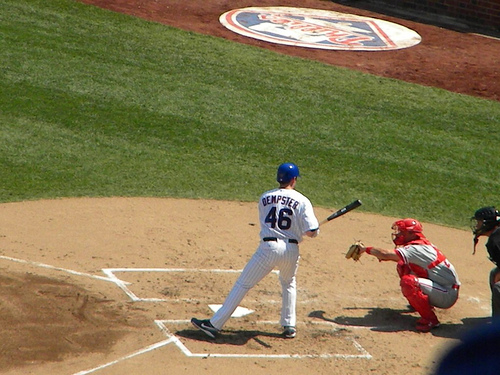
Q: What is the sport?
A: Baseball.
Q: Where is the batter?
A: In front of the catcher.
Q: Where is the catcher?
A: Behind the batter.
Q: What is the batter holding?
A: A baseball bat.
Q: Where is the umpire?
A: Behind the catcher.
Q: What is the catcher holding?
A: A catcher's mitt.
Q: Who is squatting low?
A: The catcher.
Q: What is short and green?
A: The grass.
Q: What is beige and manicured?
A: The dirt.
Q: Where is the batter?
A: At the plate.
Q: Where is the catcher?
A: Behind batter.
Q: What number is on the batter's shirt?
A: 46.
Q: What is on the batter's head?
A: Helmet.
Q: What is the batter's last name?
A: Dempster.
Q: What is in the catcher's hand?
A: Baseball glove.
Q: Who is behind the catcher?
A: Umpire.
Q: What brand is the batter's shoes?
A: Nike.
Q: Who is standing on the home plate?
A: Batter.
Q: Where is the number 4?
A: On the uniform.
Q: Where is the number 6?
A: On the uniform.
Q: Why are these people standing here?
A: They are playing baseball.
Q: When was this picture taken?
A: Summertime.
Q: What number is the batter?
A: 46.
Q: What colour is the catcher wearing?
A: Red and grey.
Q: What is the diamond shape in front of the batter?
A: Home Plate.